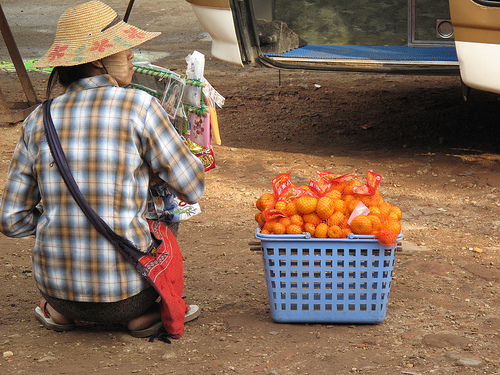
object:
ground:
[0, 0, 500, 375]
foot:
[37, 299, 73, 324]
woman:
[0, 0, 214, 331]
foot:
[128, 303, 191, 331]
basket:
[254, 227, 404, 324]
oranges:
[254, 171, 402, 245]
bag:
[42, 98, 187, 339]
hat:
[28, 0, 162, 68]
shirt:
[0, 74, 206, 303]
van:
[185, 0, 500, 94]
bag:
[271, 171, 292, 198]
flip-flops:
[34, 306, 76, 331]